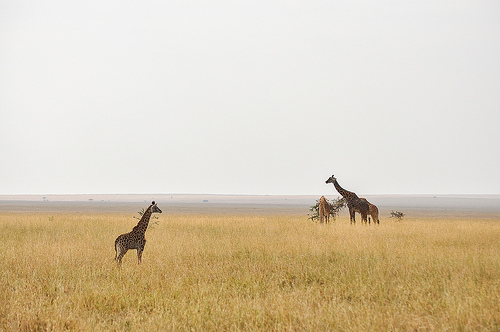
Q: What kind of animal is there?
A: Giraffe.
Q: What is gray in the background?
A: The sky.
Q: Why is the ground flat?
A: It's the horizon.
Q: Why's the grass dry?
A: No rain.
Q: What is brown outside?
A: The grass.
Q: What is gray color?
A: The sky.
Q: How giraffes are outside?
A: Several giraffes.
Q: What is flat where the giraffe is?
A: The ground.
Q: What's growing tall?
A: The grass.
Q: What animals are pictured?
A: Giraffes.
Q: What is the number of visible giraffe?
A: 3.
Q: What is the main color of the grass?
A: Brown.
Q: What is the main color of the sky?
A: Grey.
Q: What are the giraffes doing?
A: Standing.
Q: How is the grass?
A: Tall.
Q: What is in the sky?
A: Cloud.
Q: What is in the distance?
A: Plain.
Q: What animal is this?
A: Giraffe.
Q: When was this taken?
A: During the day.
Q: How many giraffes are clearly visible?
A: Two.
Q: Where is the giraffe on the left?
A: In the middle of the grass.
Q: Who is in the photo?
A: Just giraffes.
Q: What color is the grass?
A: Brown.